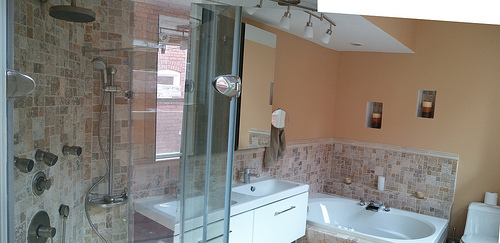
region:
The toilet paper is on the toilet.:
[477, 191, 498, 205]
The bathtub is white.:
[310, 195, 390, 242]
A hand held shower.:
[80, 41, 134, 212]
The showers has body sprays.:
[20, 122, 98, 188]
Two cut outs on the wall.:
[354, 66, 453, 146]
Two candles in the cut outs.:
[355, 63, 451, 138]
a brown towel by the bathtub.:
[268, 120, 295, 176]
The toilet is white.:
[460, 197, 487, 240]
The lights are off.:
[249, 2, 349, 61]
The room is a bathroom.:
[24, 3, 481, 238]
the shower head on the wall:
[85, 54, 116, 86]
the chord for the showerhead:
[80, 95, 120, 239]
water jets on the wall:
[5, 137, 92, 184]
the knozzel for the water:
[38, 222, 61, 242]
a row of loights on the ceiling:
[245, 0, 333, 49]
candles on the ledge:
[334, 163, 441, 210]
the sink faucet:
[237, 164, 259, 193]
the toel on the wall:
[266, 104, 288, 169]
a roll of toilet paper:
[481, 183, 498, 213]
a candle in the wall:
[414, 92, 439, 120]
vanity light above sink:
[235, 2, 259, 22]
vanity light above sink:
[278, 15, 293, 32]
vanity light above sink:
[303, 26, 315, 44]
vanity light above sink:
[321, 30, 346, 51]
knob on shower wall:
[63, 142, 85, 162]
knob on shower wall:
[16, 157, 33, 177]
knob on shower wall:
[39, 150, 66, 175]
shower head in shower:
[41, 2, 109, 32]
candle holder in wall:
[358, 97, 386, 131]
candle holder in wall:
[408, 84, 434, 126]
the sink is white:
[397, 222, 409, 237]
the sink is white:
[354, 230, 367, 234]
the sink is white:
[391, 227, 402, 242]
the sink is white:
[408, 232, 415, 242]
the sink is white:
[390, 216, 402, 241]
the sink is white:
[382, 223, 394, 236]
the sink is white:
[393, 224, 395, 239]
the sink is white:
[384, 229, 398, 240]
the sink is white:
[383, 215, 393, 242]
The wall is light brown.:
[455, 52, 487, 123]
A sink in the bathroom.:
[233, 160, 306, 206]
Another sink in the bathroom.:
[156, 185, 231, 222]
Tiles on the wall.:
[337, 151, 434, 193]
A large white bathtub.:
[311, 185, 421, 240]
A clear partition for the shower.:
[15, 11, 232, 239]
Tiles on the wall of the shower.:
[16, 41, 87, 124]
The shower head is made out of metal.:
[87, 45, 133, 120]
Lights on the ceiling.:
[236, 0, 356, 52]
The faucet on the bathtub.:
[348, 191, 400, 220]